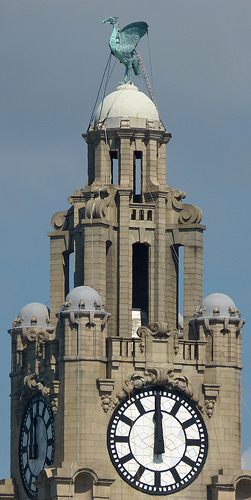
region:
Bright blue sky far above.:
[23, 81, 71, 159]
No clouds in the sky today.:
[171, 48, 235, 148]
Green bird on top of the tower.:
[100, 7, 156, 87]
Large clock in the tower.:
[103, 373, 212, 498]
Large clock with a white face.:
[104, 372, 218, 494]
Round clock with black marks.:
[102, 370, 215, 497]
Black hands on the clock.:
[149, 388, 169, 457]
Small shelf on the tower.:
[201, 379, 227, 417]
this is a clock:
[120, 394, 202, 497]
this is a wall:
[59, 404, 97, 465]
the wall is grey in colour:
[68, 411, 100, 470]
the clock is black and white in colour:
[114, 408, 194, 478]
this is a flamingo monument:
[101, 17, 147, 85]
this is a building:
[9, 84, 249, 474]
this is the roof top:
[115, 84, 152, 118]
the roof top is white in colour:
[120, 80, 148, 121]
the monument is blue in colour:
[100, 15, 151, 82]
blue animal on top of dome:
[98, 13, 152, 92]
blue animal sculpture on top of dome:
[96, 12, 150, 85]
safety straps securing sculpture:
[82, 47, 120, 137]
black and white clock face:
[105, 384, 213, 498]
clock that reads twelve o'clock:
[103, 379, 211, 499]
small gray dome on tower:
[193, 290, 246, 332]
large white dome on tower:
[87, 77, 164, 123]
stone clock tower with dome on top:
[1, 81, 249, 494]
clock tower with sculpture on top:
[2, 81, 246, 498]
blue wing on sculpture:
[116, 19, 151, 54]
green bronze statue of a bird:
[101, 15, 148, 84]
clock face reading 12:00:
[105, 384, 208, 494]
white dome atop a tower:
[80, 83, 171, 143]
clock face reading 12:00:
[17, 392, 55, 498]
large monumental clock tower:
[0, 15, 249, 497]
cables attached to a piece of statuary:
[87, 28, 165, 131]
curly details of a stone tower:
[111, 319, 203, 410]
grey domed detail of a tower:
[55, 283, 109, 361]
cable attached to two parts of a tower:
[128, 148, 200, 306]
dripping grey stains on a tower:
[66, 313, 81, 498]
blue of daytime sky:
[1, 1, 249, 479]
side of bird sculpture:
[102, 15, 159, 84]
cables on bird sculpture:
[90, 16, 154, 124]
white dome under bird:
[92, 15, 160, 116]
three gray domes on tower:
[14, 285, 243, 328]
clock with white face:
[109, 387, 206, 494]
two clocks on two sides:
[19, 383, 210, 497]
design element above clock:
[108, 370, 202, 493]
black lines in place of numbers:
[116, 396, 199, 486]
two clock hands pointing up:
[152, 393, 164, 453]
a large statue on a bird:
[97, 12, 151, 82]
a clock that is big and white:
[107, 394, 199, 495]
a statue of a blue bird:
[99, 11, 154, 78]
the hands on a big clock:
[148, 400, 173, 461]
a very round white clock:
[102, 384, 203, 490]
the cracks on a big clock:
[138, 428, 151, 454]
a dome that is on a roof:
[196, 298, 238, 329]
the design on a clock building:
[116, 366, 195, 398]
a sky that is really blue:
[0, 370, 17, 427]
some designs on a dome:
[63, 305, 106, 335]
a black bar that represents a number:
[162, 402, 182, 419]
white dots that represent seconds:
[162, 475, 178, 499]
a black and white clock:
[103, 377, 213, 498]